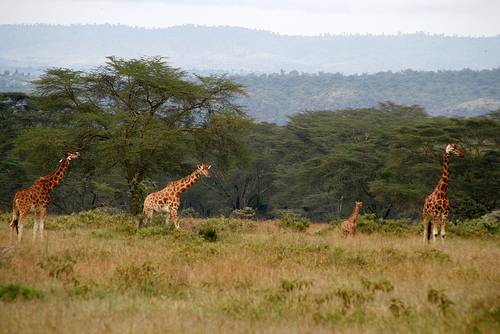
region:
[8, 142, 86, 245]
giraffe in profile head turned up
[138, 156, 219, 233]
giraffe in profile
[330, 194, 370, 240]
giraffe in distance turned forward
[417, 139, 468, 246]
giraffe facing forward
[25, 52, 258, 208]
single tree close by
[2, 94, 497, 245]
line of trees beyond field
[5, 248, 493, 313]
field with tall brown grass and green brush mixed in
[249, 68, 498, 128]
wooded rise in the mid-distance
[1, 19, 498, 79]
significant rise, wooded, in the far distance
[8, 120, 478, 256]
a group of four giraffes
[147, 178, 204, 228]
giraffe in the field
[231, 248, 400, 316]
yellow straw in field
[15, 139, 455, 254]
giraffes in the field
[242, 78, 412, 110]
trees on the mountain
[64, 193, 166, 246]
grass near the giraffe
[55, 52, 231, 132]
trees above the grass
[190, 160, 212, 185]
head of the giraffe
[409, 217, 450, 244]
legs of the giraffe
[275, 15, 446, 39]
the sky is white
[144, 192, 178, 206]
spots on the giraffe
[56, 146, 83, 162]
head of a giraffe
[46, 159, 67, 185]
neck of a giraffe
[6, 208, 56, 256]
legs of a giraffe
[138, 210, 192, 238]
legs of a giraffe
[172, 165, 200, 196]
neck of a giraffe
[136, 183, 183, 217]
body of a giraffe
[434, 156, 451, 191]
neck of a giraffe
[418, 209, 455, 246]
legs of a giraffe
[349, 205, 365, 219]
neck of a giraffe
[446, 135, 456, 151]
ear of a giraffe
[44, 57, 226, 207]
tall and green tree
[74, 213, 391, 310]
light brown grass on field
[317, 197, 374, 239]
small giraffe in distance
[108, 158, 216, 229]
giraffe has head bent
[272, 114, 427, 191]
thick stand of trees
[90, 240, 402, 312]
brown and wavy grass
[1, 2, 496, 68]
hazy sky over gently curved mountains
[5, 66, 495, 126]
trees growing on sloped land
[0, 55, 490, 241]
feathery green trees forming wall behind giraffes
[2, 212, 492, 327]
tall tan grasslands with green plants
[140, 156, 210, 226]
giraffe leaning neck forward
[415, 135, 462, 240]
head turned to side while standing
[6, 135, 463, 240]
one animal farther back than the others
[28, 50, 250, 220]
layers of branches on large tree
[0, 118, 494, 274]
a group of giraffes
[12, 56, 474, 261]
animals in the background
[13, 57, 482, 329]
giraffes in the background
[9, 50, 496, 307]
four giraffes in the background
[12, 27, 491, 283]
tall trees in the background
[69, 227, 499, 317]
grass on the ground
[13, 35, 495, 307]
forest in the background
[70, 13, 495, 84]
clear white sky in the background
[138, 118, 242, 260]
spots on the giraffe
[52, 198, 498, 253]
bushes in the background